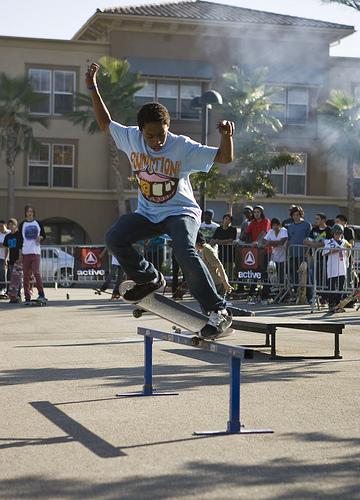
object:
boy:
[84, 61, 235, 338]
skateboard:
[119, 280, 234, 338]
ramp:
[115, 327, 274, 435]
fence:
[0, 245, 359, 313]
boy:
[322, 225, 352, 313]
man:
[18, 205, 45, 301]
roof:
[99, 0, 356, 26]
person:
[262, 218, 288, 284]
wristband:
[87, 84, 97, 89]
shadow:
[27, 396, 209, 459]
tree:
[0, 75, 48, 216]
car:
[40, 247, 75, 288]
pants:
[23, 254, 44, 300]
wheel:
[133, 309, 142, 318]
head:
[137, 103, 170, 152]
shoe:
[199, 308, 233, 340]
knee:
[104, 231, 118, 251]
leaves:
[31, 116, 49, 130]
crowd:
[200, 207, 355, 313]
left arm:
[189, 133, 233, 163]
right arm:
[90, 87, 137, 139]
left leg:
[168, 217, 227, 312]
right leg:
[105, 212, 160, 282]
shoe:
[123, 270, 166, 302]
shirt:
[109, 120, 220, 224]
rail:
[138, 327, 255, 360]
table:
[233, 317, 345, 360]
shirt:
[18, 219, 46, 254]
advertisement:
[74, 246, 109, 275]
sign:
[236, 247, 265, 279]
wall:
[80, 135, 107, 190]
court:
[0, 308, 360, 499]